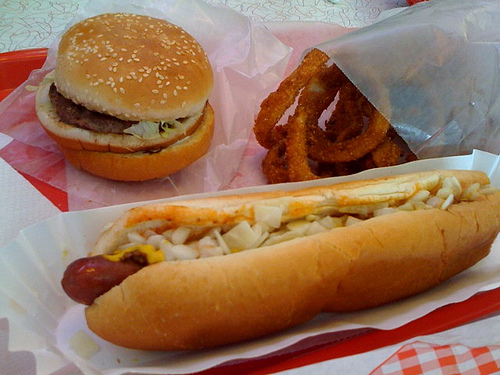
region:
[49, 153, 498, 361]
A HOT DOG WITH ONIONS AND MUSTARD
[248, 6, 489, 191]
A PACK OF ONION RINGS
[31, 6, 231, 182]
A HAMBURGER WITH ONION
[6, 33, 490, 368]
A RED TRAY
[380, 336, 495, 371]
A RED AND WHITE CHECKER TABLE CLOTH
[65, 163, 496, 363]
A HOT DOG BUN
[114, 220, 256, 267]
ONIONS AND MUSTARD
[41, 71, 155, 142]
A HAMBURGER PATTY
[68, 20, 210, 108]
SESAME SEEDS ON A BUN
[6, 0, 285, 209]
WAX PAPER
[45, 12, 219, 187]
Burger with lettuce on a bun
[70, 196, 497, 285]
Footlong hot dog with mustard and onions on a bun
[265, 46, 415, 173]
Crispy fried onion rings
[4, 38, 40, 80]
Red plastic tray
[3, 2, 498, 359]
A lunch tray with a hotdog, hamburger, and onion rings.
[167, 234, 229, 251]
Chopped white onions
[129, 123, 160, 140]
Green Lettuce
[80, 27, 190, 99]
The top of a hamburger bun with sesame seeds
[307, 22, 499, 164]
Clear greasy bag holding onion rings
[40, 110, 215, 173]
Two bottoms of a hamburger bun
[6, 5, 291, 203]
burger on paper wrapper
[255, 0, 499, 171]
onion rings in package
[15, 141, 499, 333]
hot dog in paper holder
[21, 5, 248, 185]
three burger rolls on one burger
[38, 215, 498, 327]
sausage on hot dog roll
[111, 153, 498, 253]
chopped onions on hot dog roll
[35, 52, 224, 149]
burger pattie on burger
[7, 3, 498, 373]
red tray with food on it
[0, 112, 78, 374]
white paper napkins on tray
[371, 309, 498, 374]
red checkered cloth on tray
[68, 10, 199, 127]
A toasted sesame seed sandwich bun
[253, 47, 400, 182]
Crispy french fried onion rings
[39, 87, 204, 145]
A hamburger on a bun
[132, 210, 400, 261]
Chopped onions on a roll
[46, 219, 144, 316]
A grilled hotdog on a roll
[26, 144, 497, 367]
Hotdog in a white paper holder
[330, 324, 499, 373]
A red and white checked tablecloth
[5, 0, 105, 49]
Table with golden scroll work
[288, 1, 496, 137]
Clear plastic bag to hold food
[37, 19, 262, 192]
Toasted triple decker lunch sandwich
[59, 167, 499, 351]
hot dog covered with onions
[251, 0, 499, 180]
onion rings in bag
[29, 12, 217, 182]
hamburger next to onion rings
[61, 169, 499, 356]
hot dog in bun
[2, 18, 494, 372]
food sitting on red tray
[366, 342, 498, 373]
red and white checkered paper under hot dog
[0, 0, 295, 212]
hamburger sitting on clear paper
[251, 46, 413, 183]
brown onion rings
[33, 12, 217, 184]
lettuce on hamburger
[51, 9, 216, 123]
sesame seed bun on hamburger